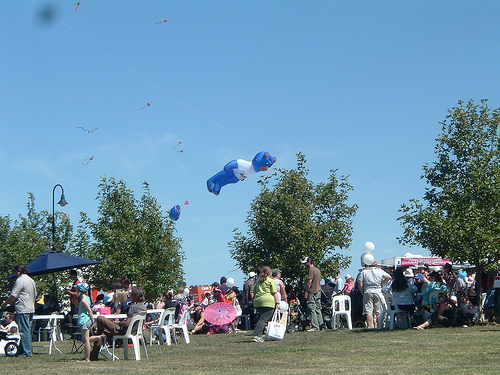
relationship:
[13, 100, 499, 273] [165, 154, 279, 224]
trees near balloon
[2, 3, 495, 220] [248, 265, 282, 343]
sky above woman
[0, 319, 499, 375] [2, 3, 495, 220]
grass below sky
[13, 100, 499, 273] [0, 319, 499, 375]
trees above grass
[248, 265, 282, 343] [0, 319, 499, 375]
woman on grass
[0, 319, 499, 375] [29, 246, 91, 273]
grass under umbrella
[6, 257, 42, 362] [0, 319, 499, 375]
man on grass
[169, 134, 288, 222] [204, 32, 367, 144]
kite in sky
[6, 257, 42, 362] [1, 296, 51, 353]
man wearing jeans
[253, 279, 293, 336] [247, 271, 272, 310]
woman wearing shirt